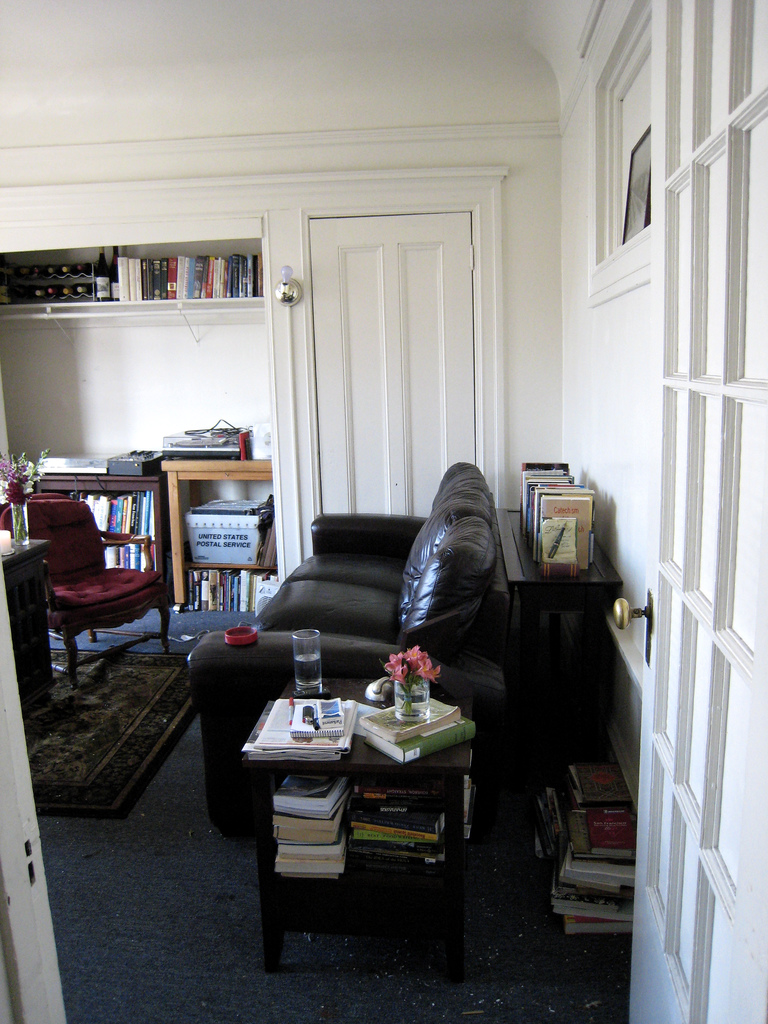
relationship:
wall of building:
[1, 0, 766, 806] [112, 57, 268, 104]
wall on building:
[1, 0, 766, 806] [103, 119, 709, 759]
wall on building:
[1, 0, 766, 806] [44, 42, 644, 756]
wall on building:
[1, 74, 562, 542] [149, 154, 667, 542]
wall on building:
[1, 74, 562, 542] [30, 111, 729, 1021]